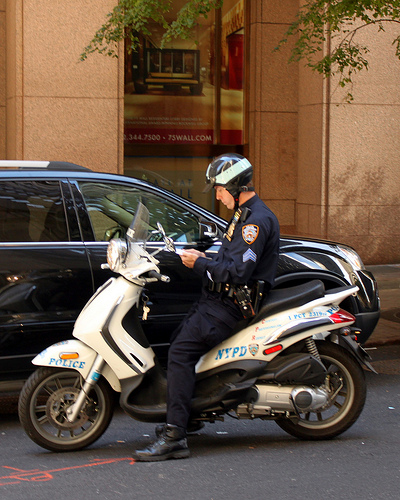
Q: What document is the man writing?
A: A ticket.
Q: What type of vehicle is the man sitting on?
A: A moped.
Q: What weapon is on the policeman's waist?
A: A gun.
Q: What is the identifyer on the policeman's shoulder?
A: A badge.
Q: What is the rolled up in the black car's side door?
A: Windows.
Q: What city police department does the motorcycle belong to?
A: NYPD.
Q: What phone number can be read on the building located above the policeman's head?
A: 344 7300.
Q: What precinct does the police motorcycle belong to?
A: 1 PCT.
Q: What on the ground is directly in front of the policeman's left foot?
A: A spray painted arrow.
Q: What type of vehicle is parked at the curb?
A: SUV.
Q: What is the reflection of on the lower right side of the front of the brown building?
A: Tree branches and leaves.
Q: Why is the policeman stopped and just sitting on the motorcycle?
A: Looking at something in hands..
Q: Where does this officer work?
A: New York Police Department.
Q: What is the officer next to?
A: A car.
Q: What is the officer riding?
A: A motorcycle.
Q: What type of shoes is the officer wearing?
A: Boots.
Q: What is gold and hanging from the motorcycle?
A: Keys.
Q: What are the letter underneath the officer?
A: NYPD.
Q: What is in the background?
A: A building.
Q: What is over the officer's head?
A: Tree limbs.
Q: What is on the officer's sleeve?
A: Patches.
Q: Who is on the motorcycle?
A: The police man.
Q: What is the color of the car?
A: Black.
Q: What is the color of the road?
A: Grey.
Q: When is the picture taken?
A: Daytime.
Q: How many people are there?
A: 1.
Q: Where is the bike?
A: Road.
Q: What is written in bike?
A: NYPD.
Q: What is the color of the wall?
A: Red.